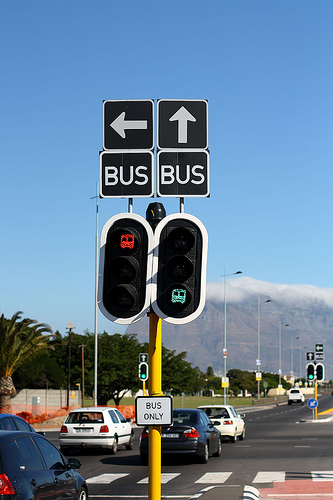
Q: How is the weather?
A: It is clear.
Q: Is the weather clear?
A: Yes, it is clear.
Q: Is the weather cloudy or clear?
A: It is clear.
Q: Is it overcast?
A: No, it is clear.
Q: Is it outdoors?
A: Yes, it is outdoors.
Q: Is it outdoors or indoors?
A: It is outdoors.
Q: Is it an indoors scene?
A: No, it is outdoors.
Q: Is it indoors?
A: No, it is outdoors.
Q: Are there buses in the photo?
A: Yes, there is a bus.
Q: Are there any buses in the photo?
A: Yes, there is a bus.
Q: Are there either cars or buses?
A: Yes, there is a bus.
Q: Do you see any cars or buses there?
A: Yes, there is a bus.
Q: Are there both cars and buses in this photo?
A: Yes, there are both a bus and a car.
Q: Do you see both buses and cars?
A: Yes, there are both a bus and a car.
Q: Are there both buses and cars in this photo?
A: Yes, there are both a bus and a car.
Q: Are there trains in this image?
A: No, there are no trains.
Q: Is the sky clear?
A: Yes, the sky is clear.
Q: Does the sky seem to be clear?
A: Yes, the sky is clear.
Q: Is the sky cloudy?
A: No, the sky is clear.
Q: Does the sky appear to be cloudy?
A: No, the sky is clear.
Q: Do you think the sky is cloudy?
A: No, the sky is clear.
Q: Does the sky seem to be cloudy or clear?
A: The sky is clear.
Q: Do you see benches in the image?
A: No, there are no benches.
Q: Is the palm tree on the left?
A: Yes, the palm tree is on the left of the image.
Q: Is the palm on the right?
A: No, the palm is on the left of the image.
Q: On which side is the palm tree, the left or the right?
A: The palm tree is on the left of the image.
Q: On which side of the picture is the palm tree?
A: The palm tree is on the left of the image.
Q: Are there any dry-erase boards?
A: No, there are no dry-erase boards.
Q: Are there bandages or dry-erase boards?
A: No, there are no dry-erase boards or bandages.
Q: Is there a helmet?
A: No, there are no helmets.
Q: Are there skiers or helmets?
A: No, there are no helmets or skiers.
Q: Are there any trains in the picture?
A: No, there are no trains.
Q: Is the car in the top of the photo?
A: No, the car is in the bottom of the image.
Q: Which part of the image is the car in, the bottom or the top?
A: The car is in the bottom of the image.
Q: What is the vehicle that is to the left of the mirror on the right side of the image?
A: The vehicle is a car.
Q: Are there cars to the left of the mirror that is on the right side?
A: Yes, there is a car to the left of the mirror.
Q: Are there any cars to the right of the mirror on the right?
A: No, the car is to the left of the mirror.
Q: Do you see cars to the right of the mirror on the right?
A: No, the car is to the left of the mirror.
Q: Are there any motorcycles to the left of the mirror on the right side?
A: No, there is a car to the left of the mirror.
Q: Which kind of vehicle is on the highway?
A: The vehicle is a car.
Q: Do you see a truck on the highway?
A: No, there is a car on the highway.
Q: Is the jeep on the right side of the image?
A: Yes, the jeep is on the right of the image.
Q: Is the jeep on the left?
A: No, the jeep is on the right of the image.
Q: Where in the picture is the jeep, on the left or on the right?
A: The jeep is on the right of the image.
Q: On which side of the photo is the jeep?
A: The jeep is on the right of the image.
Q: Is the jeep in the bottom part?
A: Yes, the jeep is in the bottom of the image.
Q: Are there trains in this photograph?
A: No, there are no trains.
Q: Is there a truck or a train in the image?
A: No, there are no trains or trucks.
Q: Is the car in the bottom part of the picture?
A: Yes, the car is in the bottom of the image.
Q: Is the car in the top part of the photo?
A: No, the car is in the bottom of the image.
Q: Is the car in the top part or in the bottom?
A: The car is in the bottom of the image.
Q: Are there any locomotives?
A: No, there are no locomotives.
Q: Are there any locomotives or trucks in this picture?
A: No, there are no locomotives or trucks.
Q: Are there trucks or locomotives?
A: No, there are no locomotives or trucks.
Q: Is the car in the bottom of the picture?
A: Yes, the car is in the bottom of the image.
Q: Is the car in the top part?
A: No, the car is in the bottom of the image.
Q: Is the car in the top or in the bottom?
A: The car is in the bottom of the image.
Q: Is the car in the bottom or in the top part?
A: The car is in the bottom of the image.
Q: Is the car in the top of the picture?
A: No, the car is in the bottom of the image.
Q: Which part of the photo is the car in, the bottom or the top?
A: The car is in the bottom of the image.